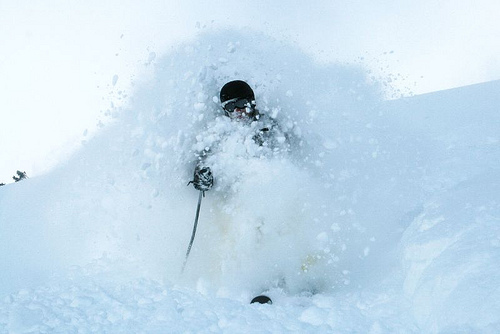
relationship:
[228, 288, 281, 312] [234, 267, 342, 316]
tip of ski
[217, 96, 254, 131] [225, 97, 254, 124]
snow on person face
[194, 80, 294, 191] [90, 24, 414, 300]
person skiing through snow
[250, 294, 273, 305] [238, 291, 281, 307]
tip of a ski